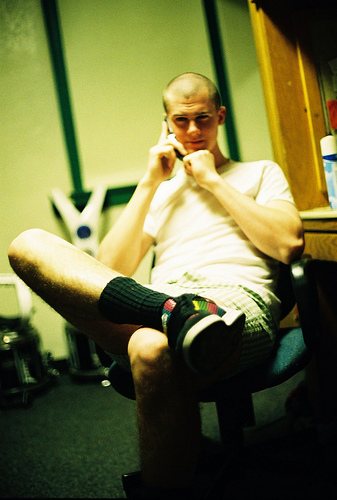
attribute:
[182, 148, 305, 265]
arm — man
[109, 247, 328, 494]
office chair — green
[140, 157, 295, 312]
shirt — white, tee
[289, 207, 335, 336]
desk — WOODEN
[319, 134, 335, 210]
bottle — white, blue, aerosol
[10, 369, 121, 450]
green carpet — dark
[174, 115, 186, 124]
eye — man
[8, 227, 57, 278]
knee — man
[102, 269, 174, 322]
sock — black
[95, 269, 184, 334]
sock — BLACK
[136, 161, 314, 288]
shirt — white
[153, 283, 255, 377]
shoes — colorful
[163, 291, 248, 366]
black shoe — red, green, yellow, blue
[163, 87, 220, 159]
face — man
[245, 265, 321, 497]
chair — OFFICE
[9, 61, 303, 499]
man — YOUNG, BLUE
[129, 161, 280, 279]
t-shirt — WHITE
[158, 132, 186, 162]
phone — CELL